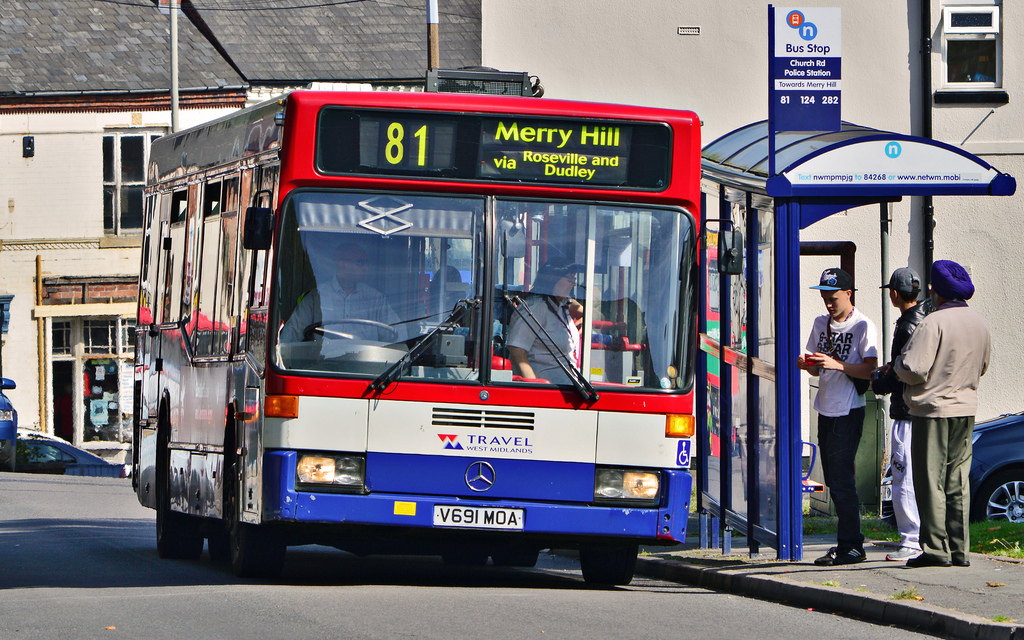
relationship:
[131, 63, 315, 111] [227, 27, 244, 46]
shingle on roof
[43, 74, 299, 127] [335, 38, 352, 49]
shingle on roof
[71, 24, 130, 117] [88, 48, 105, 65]
shingle on roof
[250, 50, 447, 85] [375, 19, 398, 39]
shingle on roof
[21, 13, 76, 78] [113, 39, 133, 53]
shingle on roof